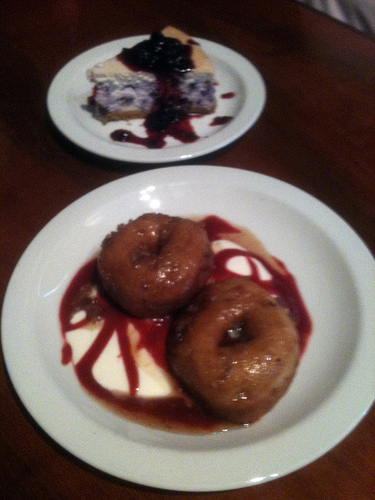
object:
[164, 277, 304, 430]
doughnuts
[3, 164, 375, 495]
plate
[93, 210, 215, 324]
doughnuts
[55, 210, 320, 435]
sauce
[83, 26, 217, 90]
dessert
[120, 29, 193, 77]
sauce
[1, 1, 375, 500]
table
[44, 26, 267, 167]
plate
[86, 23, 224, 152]
food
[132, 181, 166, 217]
reflection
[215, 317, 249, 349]
hole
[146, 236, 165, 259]
hole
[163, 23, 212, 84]
crust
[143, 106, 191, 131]
fruit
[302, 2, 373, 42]
someone